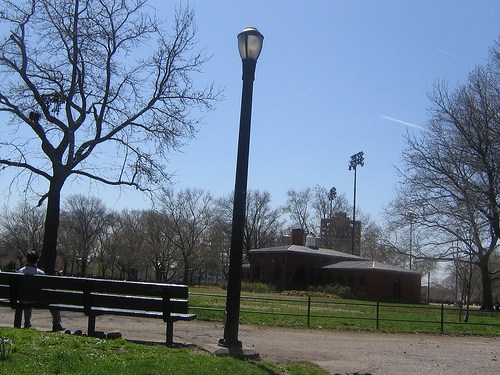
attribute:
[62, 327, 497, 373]
road — grey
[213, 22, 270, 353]
streetlight — old fashioned, decorative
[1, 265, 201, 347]
bench — green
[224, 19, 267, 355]
light post — tall, black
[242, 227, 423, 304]
structure — building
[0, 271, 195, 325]
bench — long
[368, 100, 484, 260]
tree — leafless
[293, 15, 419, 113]
sky — blue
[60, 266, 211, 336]
bench — wooden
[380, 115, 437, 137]
marking — white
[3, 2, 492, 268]
sky — blue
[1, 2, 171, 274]
tree — leafless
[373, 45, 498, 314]
tree — leafless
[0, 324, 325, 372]
area — grassy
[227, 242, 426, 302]
building — brick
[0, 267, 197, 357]
bench — long